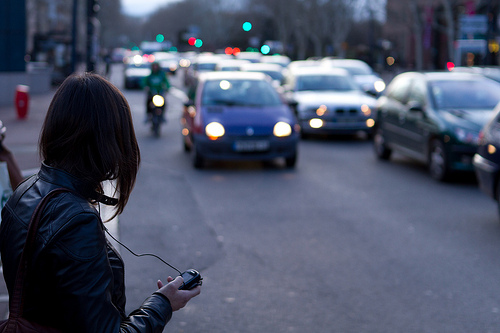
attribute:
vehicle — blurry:
[184, 70, 297, 170]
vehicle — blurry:
[284, 64, 371, 134]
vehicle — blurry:
[376, 70, 479, 181]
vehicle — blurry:
[147, 86, 169, 139]